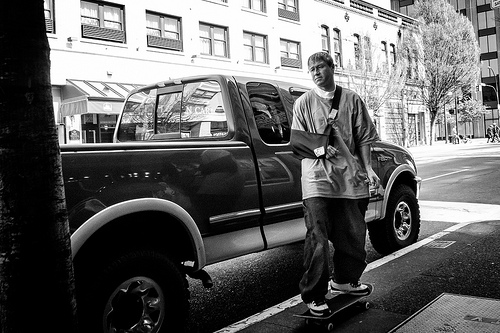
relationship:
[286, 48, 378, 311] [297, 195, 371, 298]
boy wears jeans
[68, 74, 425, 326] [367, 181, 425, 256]
truck has tire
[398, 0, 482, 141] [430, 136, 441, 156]
tree has trunk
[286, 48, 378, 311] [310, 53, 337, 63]
man has hair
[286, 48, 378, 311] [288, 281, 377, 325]
boy on skateboard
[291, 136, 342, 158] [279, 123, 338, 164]
arm in sling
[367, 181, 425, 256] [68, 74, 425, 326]
tire of truck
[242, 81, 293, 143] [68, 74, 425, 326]
window of truck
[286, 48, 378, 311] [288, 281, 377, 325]
boy wears sneakers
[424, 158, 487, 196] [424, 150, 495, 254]
line on street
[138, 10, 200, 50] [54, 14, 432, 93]
window in building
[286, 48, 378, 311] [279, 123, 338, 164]
boy wearing sling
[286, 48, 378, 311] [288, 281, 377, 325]
boy riding skateboard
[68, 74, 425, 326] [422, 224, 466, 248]
truck parked by curb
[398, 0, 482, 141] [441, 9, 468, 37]
tree has leaves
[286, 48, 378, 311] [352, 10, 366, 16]
boy wearing glasses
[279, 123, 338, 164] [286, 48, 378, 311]
sling worn by boy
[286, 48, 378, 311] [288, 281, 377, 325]
boy rides skateboard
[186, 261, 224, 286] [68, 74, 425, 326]
pipe on truck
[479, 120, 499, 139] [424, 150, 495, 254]
people walking across street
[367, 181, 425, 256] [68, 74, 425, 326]
tire from truck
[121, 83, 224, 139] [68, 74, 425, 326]
rear windshield from truck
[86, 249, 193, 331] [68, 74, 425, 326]
rear tire of truck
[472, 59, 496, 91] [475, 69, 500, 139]
lights on lamp post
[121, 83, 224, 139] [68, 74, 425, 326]
rear windshield of truck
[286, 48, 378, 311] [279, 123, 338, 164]
boy in sling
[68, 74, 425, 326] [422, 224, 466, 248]
truck parked on curb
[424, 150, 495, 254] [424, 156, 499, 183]
street has two lanes